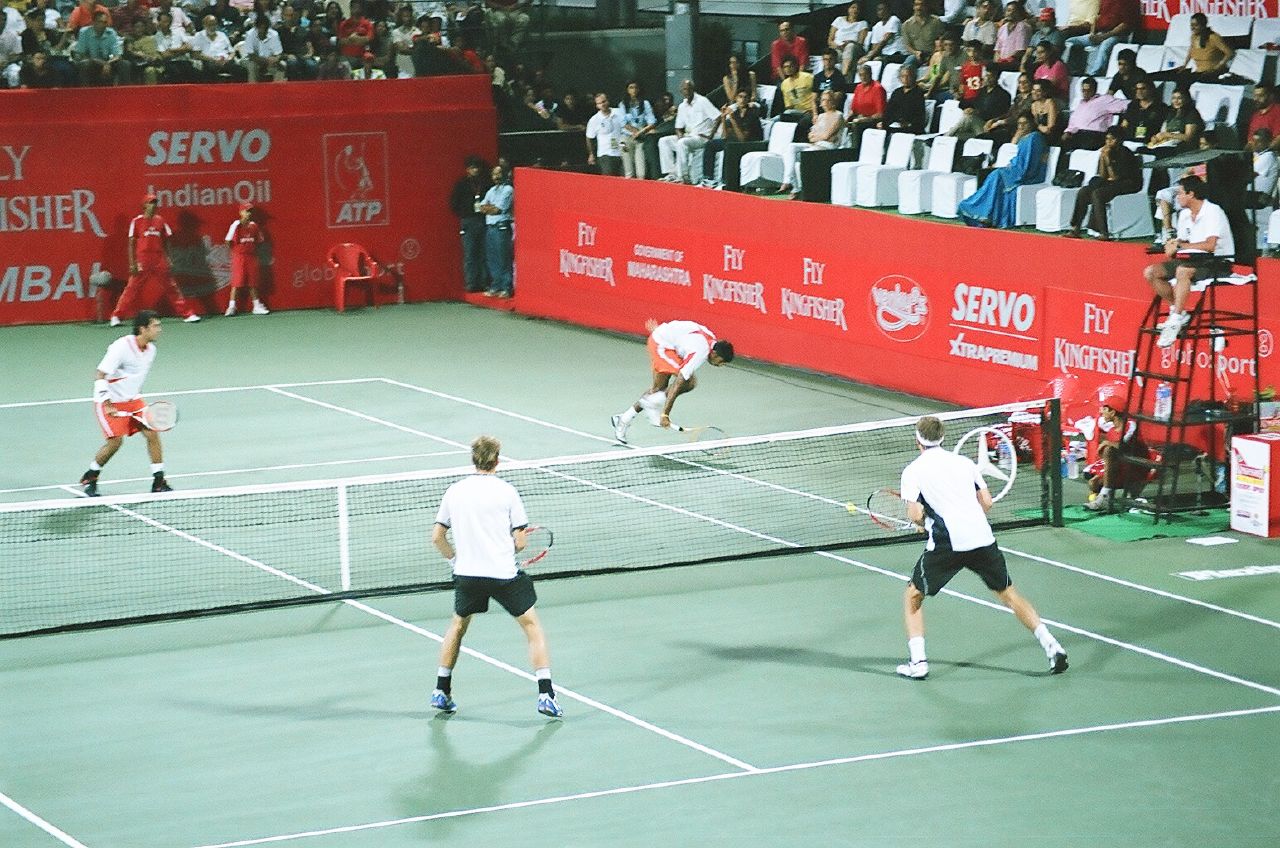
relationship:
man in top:
[429, 434, 563, 720] [431, 493, 559, 574]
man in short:
[429, 434, 563, 720] [438, 558, 575, 625]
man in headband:
[429, 434, 563, 720] [894, 381, 1010, 457]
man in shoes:
[429, 434, 563, 720] [871, 607, 1131, 730]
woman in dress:
[924, 88, 1054, 253] [964, 102, 1024, 260]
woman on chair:
[924, 88, 1054, 253] [959, 90, 1073, 273]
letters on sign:
[924, 246, 1047, 401] [496, 90, 1205, 504]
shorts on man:
[887, 535, 1089, 644] [817, 332, 1079, 734]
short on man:
[451, 570, 538, 620] [394, 367, 654, 788]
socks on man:
[510, 660, 565, 701] [310, 397, 652, 776]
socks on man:
[864, 609, 1129, 669] [838, 344, 1121, 802]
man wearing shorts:
[413, 425, 578, 722] [432, 556, 534, 614]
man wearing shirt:
[429, 434, 563, 720] [420, 474, 534, 588]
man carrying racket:
[429, 434, 563, 720] [425, 472, 543, 588]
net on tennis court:
[0, 379, 1065, 648] [4, 297, 1279, 843]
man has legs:
[99, 195, 208, 343] [97, 260, 213, 322]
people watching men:
[6, 11, 1272, 239] [69, 272, 1076, 718]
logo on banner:
[544, 211, 620, 292] [504, 162, 1274, 450]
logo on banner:
[621, 232, 693, 299] [504, 162, 1274, 450]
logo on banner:
[702, 232, 774, 332] [502, 151, 1279, 420]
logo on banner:
[772, 239, 862, 343] [502, 167, 1276, 509]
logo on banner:
[858, 267, 937, 348] [504, 162, 1274, 450]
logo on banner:
[932, 272, 1055, 383] [504, 162, 1274, 450]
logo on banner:
[1042, 290, 1160, 408] [502, 151, 1279, 420]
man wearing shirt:
[881, 423, 1076, 679] [897, 446, 1006, 550]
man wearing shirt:
[609, 297, 746, 436] [660, 314, 713, 376]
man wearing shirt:
[429, 434, 563, 720] [434, 463, 534, 588]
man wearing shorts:
[429, 434, 563, 720] [458, 570, 548, 609]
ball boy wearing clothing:
[218, 181, 280, 327] [216, 209, 269, 302]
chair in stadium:
[863, 121, 918, 207] [1, 11, 1274, 844]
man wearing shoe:
[429, 434, 563, 720] [525, 670, 564, 711]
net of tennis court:
[0, 379, 1065, 648] [4, 297, 1279, 843]